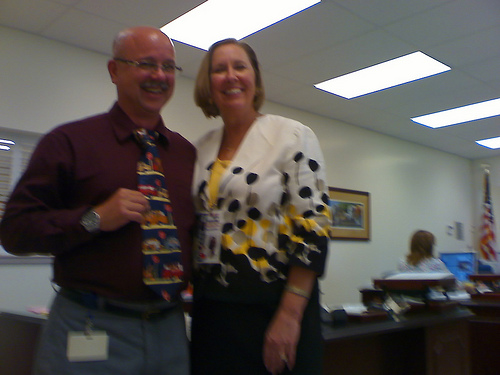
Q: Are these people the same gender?
A: No, they are both male and female.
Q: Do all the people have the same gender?
A: No, they are both male and female.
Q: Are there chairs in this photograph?
A: No, there are no chairs.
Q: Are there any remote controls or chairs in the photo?
A: No, there are no chairs or remote controls.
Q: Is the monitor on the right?
A: Yes, the monitor is on the right of the image.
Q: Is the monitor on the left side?
A: No, the monitor is on the right of the image.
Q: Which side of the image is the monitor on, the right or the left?
A: The monitor is on the right of the image.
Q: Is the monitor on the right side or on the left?
A: The monitor is on the right of the image.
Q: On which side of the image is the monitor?
A: The monitor is on the right of the image.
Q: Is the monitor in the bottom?
A: Yes, the monitor is in the bottom of the image.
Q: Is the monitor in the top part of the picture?
A: No, the monitor is in the bottom of the image.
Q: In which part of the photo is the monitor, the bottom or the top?
A: The monitor is in the bottom of the image.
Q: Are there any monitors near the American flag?
A: Yes, there is a monitor near the American flag.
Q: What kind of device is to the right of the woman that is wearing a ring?
A: The device is a monitor.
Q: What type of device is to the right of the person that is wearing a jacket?
A: The device is a monitor.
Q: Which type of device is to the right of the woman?
A: The device is a monitor.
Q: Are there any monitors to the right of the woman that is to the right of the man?
A: Yes, there is a monitor to the right of the woman.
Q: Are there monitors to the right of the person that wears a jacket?
A: Yes, there is a monitor to the right of the woman.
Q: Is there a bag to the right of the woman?
A: No, there is a monitor to the right of the woman.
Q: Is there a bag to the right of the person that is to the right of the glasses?
A: No, there is a monitor to the right of the woman.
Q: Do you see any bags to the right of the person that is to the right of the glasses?
A: No, there is a monitor to the right of the woman.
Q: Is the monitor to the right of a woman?
A: Yes, the monitor is to the right of a woman.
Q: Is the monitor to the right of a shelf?
A: No, the monitor is to the right of a woman.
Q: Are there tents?
A: No, there are no tents.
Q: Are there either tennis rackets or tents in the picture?
A: No, there are no tents or tennis rackets.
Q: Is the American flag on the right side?
A: Yes, the American flag is on the right of the image.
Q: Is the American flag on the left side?
A: No, the American flag is on the right of the image.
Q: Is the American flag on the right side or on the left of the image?
A: The American flag is on the right of the image.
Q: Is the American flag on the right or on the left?
A: The American flag is on the right of the image.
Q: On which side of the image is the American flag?
A: The American flag is on the right of the image.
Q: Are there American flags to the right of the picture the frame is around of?
A: Yes, there is an American flag to the right of the picture.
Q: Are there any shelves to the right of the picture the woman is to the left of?
A: No, there is an American flag to the right of the picture.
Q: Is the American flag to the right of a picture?
A: Yes, the American flag is to the right of a picture.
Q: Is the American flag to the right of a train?
A: No, the American flag is to the right of a picture.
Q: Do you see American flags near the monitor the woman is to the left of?
A: Yes, there is an American flag near the monitor.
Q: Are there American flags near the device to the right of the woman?
A: Yes, there is an American flag near the monitor.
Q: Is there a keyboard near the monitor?
A: No, there is an American flag near the monitor.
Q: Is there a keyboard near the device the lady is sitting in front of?
A: No, there is an American flag near the monitor.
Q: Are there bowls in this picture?
A: No, there are no bowls.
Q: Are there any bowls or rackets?
A: No, there are no bowls or rackets.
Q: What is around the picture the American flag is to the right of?
A: The frame is around the picture.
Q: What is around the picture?
A: The frame is around the picture.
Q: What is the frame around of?
A: The frame is around the picture.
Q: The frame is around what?
A: The frame is around the picture.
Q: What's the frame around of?
A: The frame is around the picture.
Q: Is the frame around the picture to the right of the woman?
A: Yes, the frame is around the picture.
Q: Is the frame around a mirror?
A: No, the frame is around the picture.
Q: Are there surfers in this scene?
A: No, there are no surfers.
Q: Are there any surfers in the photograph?
A: No, there are no surfers.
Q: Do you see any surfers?
A: No, there are no surfers.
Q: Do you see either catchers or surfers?
A: No, there are no surfers or catchers.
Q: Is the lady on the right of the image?
A: Yes, the lady is on the right of the image.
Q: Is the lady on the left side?
A: No, the lady is on the right of the image.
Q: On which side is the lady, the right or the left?
A: The lady is on the right of the image.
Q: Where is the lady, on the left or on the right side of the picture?
A: The lady is on the right of the image.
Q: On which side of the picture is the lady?
A: The lady is on the right of the image.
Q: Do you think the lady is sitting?
A: Yes, the lady is sitting.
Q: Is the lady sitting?
A: Yes, the lady is sitting.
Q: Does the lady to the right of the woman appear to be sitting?
A: Yes, the lady is sitting.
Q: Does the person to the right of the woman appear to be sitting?
A: Yes, the lady is sitting.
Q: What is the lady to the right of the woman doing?
A: The lady is sitting.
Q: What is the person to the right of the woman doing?
A: The lady is sitting.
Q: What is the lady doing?
A: The lady is sitting.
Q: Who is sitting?
A: The lady is sitting.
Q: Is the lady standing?
A: No, the lady is sitting.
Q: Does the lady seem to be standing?
A: No, the lady is sitting.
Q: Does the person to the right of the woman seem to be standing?
A: No, the lady is sitting.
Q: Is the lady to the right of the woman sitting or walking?
A: The lady is sitting.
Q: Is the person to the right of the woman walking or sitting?
A: The lady is sitting.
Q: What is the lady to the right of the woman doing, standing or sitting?
A: The lady is sitting.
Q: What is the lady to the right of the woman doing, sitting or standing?
A: The lady is sitting.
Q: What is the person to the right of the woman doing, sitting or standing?
A: The lady is sitting.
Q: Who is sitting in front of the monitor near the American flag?
A: The lady is sitting in front of the monitor.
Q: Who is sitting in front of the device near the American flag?
A: The lady is sitting in front of the monitor.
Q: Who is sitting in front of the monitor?
A: The lady is sitting in front of the monitor.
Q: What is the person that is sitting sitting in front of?
A: The lady is sitting in front of the monitor.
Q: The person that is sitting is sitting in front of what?
A: The lady is sitting in front of the monitor.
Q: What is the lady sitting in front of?
A: The lady is sitting in front of the monitor.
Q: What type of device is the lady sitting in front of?
A: The lady is sitting in front of the monitor.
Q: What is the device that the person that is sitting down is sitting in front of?
A: The device is a monitor.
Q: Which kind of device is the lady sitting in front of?
A: The lady is sitting in front of the monitor.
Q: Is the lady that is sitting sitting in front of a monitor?
A: Yes, the lady is sitting in front of a monitor.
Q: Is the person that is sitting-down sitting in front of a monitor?
A: Yes, the lady is sitting in front of a monitor.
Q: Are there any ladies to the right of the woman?
A: Yes, there is a lady to the right of the woman.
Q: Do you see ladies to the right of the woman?
A: Yes, there is a lady to the right of the woman.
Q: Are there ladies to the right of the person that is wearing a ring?
A: Yes, there is a lady to the right of the woman.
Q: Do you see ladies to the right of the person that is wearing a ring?
A: Yes, there is a lady to the right of the woman.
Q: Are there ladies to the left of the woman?
A: No, the lady is to the right of the woman.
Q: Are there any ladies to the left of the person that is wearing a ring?
A: No, the lady is to the right of the woman.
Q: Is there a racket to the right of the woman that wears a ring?
A: No, there is a lady to the right of the woman.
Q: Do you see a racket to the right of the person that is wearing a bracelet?
A: No, there is a lady to the right of the woman.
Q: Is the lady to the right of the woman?
A: Yes, the lady is to the right of the woman.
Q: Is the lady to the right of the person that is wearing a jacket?
A: Yes, the lady is to the right of the woman.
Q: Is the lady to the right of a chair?
A: No, the lady is to the right of the woman.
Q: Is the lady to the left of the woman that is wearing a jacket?
A: No, the lady is to the right of the woman.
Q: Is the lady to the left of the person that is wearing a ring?
A: No, the lady is to the right of the woman.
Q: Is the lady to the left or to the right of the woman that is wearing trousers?
A: The lady is to the right of the woman.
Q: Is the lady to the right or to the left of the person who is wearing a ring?
A: The lady is to the right of the woman.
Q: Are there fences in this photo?
A: No, there are no fences.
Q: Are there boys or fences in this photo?
A: No, there are no fences or boys.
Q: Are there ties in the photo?
A: Yes, there is a tie.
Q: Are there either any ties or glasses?
A: Yes, there is a tie.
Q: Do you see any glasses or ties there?
A: Yes, there is a tie.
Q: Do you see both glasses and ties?
A: Yes, there are both a tie and glasses.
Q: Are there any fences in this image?
A: No, there are no fences.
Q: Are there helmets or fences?
A: No, there are no fences or helmets.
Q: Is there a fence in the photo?
A: No, there are no fences.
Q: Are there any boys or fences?
A: No, there are no fences or boys.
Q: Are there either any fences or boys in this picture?
A: No, there are no fences or boys.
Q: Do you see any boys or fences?
A: No, there are no fences or boys.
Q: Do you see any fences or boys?
A: No, there are no fences or boys.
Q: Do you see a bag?
A: No, there are no bags.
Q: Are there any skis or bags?
A: No, there are no bags or skis.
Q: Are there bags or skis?
A: No, there are no bags or skis.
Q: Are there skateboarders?
A: No, there are no skateboarders.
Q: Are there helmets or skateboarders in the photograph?
A: No, there are no skateboarders or helmets.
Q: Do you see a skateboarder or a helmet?
A: No, there are no skateboarders or helmets.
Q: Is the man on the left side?
A: Yes, the man is on the left of the image.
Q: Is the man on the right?
A: No, the man is on the left of the image.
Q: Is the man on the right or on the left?
A: The man is on the left of the image.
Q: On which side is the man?
A: The man is on the left of the image.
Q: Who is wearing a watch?
A: The man is wearing a watch.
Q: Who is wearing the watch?
A: The man is wearing a watch.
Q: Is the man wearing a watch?
A: Yes, the man is wearing a watch.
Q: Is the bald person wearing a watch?
A: Yes, the man is wearing a watch.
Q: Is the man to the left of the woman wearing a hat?
A: No, the man is wearing a watch.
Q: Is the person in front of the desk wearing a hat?
A: No, the man is wearing a watch.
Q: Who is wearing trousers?
A: The man is wearing trousers.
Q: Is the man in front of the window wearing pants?
A: Yes, the man is wearing pants.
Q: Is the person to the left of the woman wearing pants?
A: Yes, the man is wearing pants.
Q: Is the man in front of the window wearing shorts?
A: No, the man is wearing pants.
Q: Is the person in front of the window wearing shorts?
A: No, the man is wearing pants.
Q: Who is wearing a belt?
A: The man is wearing a belt.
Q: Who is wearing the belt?
A: The man is wearing a belt.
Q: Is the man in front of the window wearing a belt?
A: Yes, the man is wearing a belt.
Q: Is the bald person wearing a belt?
A: Yes, the man is wearing a belt.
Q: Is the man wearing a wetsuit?
A: No, the man is wearing a belt.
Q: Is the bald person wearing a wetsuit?
A: No, the man is wearing a belt.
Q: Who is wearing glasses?
A: The man is wearing glasses.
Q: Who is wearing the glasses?
A: The man is wearing glasses.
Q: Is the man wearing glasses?
A: Yes, the man is wearing glasses.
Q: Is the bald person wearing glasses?
A: Yes, the man is wearing glasses.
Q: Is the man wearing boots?
A: No, the man is wearing glasses.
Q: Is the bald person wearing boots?
A: No, the man is wearing glasses.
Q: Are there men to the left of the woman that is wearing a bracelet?
A: Yes, there is a man to the left of the woman.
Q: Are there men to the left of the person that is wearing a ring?
A: Yes, there is a man to the left of the woman.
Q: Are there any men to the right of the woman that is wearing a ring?
A: No, the man is to the left of the woman.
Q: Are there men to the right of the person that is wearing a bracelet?
A: No, the man is to the left of the woman.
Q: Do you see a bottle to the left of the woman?
A: No, there is a man to the left of the woman.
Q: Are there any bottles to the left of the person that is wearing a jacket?
A: No, there is a man to the left of the woman.